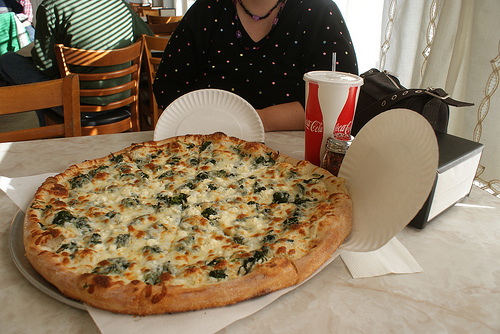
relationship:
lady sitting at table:
[153, 2, 359, 131] [4, 131, 498, 333]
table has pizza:
[4, 131, 498, 333] [21, 130, 355, 318]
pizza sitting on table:
[21, 130, 355, 318] [4, 131, 498, 333]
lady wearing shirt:
[153, 2, 359, 131] [153, 2, 361, 108]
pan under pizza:
[9, 199, 101, 312] [21, 130, 355, 318]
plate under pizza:
[338, 104, 441, 254] [21, 130, 355, 318]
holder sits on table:
[408, 137, 486, 233] [4, 131, 498, 333]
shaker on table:
[323, 133, 355, 176] [4, 131, 498, 333]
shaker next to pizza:
[323, 133, 355, 176] [21, 130, 355, 318]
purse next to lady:
[349, 67, 478, 139] [153, 2, 359, 131]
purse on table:
[349, 67, 478, 139] [4, 131, 498, 333]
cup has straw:
[303, 49, 364, 169] [331, 52, 340, 75]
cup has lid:
[303, 49, 364, 169] [302, 70, 366, 87]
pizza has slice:
[21, 130, 355, 318] [150, 200, 299, 316]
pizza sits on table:
[21, 130, 355, 318] [4, 131, 498, 333]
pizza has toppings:
[21, 130, 355, 318] [46, 141, 327, 284]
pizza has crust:
[21, 130, 355, 318] [23, 129, 355, 317]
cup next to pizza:
[303, 49, 364, 169] [21, 130, 355, 318]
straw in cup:
[331, 52, 340, 75] [303, 49, 364, 169]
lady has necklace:
[153, 2, 359, 131] [235, 1, 287, 22]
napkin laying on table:
[342, 237, 425, 282] [4, 131, 498, 333]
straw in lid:
[331, 52, 340, 75] [302, 70, 366, 87]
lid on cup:
[302, 70, 366, 87] [303, 49, 364, 169]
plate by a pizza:
[338, 104, 441, 254] [21, 130, 355, 318]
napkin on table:
[342, 237, 425, 282] [4, 131, 498, 333]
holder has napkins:
[408, 137, 486, 233] [426, 154, 482, 221]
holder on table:
[408, 137, 486, 233] [4, 131, 498, 333]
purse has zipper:
[349, 67, 478, 139] [371, 80, 427, 99]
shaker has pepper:
[323, 133, 355, 176] [326, 151, 346, 173]